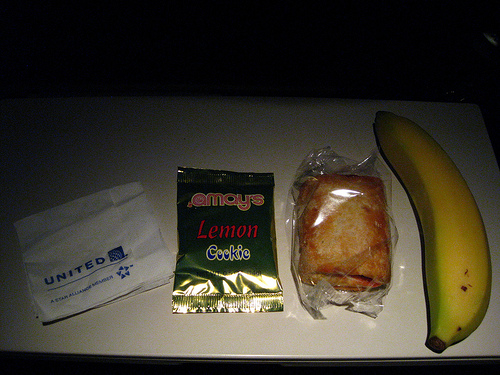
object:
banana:
[371, 108, 495, 355]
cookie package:
[168, 159, 292, 321]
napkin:
[10, 175, 181, 330]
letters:
[245, 219, 258, 240]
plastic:
[287, 142, 402, 321]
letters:
[39, 276, 57, 289]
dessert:
[289, 143, 395, 322]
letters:
[205, 243, 223, 261]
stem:
[425, 336, 451, 356]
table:
[2, 87, 499, 369]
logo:
[107, 244, 126, 264]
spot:
[457, 283, 468, 296]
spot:
[455, 324, 463, 334]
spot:
[462, 265, 470, 277]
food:
[173, 177, 283, 305]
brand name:
[184, 190, 269, 211]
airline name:
[40, 254, 111, 287]